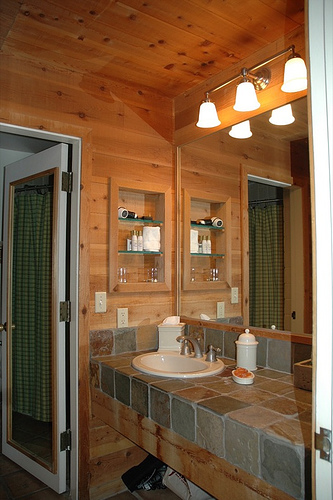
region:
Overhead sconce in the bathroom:
[196, 44, 309, 126]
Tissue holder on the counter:
[156, 315, 184, 351]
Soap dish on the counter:
[231, 365, 254, 384]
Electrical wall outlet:
[115, 306, 130, 329]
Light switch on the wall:
[93, 290, 107, 313]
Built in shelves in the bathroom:
[105, 176, 173, 294]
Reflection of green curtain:
[246, 197, 286, 330]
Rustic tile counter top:
[90, 324, 314, 499]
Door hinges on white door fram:
[59, 170, 72, 452]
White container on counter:
[234, 328, 258, 371]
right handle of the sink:
[204, 343, 221, 362]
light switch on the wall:
[91, 290, 109, 312]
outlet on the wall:
[114, 304, 130, 329]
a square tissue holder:
[155, 311, 185, 350]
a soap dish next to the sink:
[231, 363, 254, 385]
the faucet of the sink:
[176, 333, 203, 358]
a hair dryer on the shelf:
[115, 204, 154, 221]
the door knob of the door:
[0, 320, 7, 330]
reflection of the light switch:
[227, 284, 239, 305]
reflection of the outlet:
[213, 296, 228, 322]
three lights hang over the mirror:
[184, 35, 311, 129]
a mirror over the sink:
[163, 94, 328, 346]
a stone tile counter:
[87, 319, 318, 498]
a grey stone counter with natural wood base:
[87, 320, 312, 497]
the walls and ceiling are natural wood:
[14, 3, 307, 490]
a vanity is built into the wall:
[104, 175, 172, 293]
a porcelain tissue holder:
[148, 311, 187, 355]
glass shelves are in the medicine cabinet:
[116, 184, 171, 292]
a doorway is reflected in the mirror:
[233, 160, 309, 338]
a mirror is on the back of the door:
[7, 167, 60, 448]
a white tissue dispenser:
[151, 310, 190, 359]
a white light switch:
[91, 280, 111, 316]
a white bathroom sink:
[115, 333, 224, 393]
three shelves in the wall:
[98, 178, 172, 290]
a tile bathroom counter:
[144, 382, 303, 443]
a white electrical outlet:
[111, 300, 136, 334]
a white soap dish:
[226, 362, 256, 391]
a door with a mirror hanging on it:
[0, 160, 76, 420]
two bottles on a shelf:
[128, 227, 145, 255]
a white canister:
[232, 325, 268, 373]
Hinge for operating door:
[59, 170, 72, 191]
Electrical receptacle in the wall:
[117, 307, 128, 327]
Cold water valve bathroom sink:
[206, 344, 221, 361]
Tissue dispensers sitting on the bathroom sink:
[156, 316, 184, 353]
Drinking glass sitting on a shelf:
[147, 265, 158, 282]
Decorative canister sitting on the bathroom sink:
[234, 328, 257, 371]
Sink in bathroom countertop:
[129, 332, 225, 378]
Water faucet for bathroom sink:
[176, 332, 222, 362]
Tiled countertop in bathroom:
[88, 318, 312, 499]